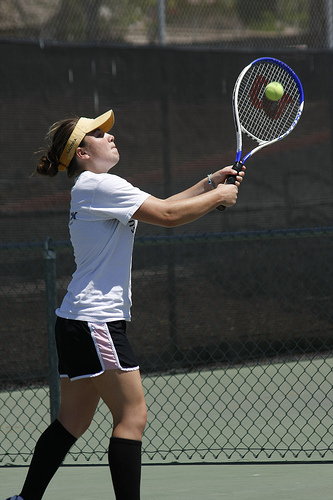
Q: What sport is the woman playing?
A: Tennis.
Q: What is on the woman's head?
A: Visor.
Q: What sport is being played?
A: Tennis.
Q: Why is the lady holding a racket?
A: To hit the ball.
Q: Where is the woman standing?
A: On a tennis court.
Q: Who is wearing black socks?
A: Tennis player.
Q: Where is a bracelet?
A: Around woman's wrist.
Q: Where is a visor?
A: On woman's head.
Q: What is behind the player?
A: A fence.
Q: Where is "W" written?
A: On tennis racket.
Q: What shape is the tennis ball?
A: Round.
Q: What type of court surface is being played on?
A: Hard.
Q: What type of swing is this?
A: Backhand.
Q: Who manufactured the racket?
A: Wilson.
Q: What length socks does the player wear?
A: Knee length.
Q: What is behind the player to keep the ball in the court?
A: A fence.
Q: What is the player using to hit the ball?
A: Tennis Racket.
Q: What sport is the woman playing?
A: Tennis.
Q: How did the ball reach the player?
A: Another player hit it.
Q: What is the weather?
A: Sunny.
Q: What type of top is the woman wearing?
A: T-shirt.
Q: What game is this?
A: Tennis.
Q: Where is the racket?
A: On the player's hands.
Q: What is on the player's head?
A: A yellow hat.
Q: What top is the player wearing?
A: A white tee.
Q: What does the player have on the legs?
A: Black socks.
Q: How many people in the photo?
A: One.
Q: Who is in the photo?
A: A woman.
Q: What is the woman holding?
A: A racket.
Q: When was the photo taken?
A: Day time.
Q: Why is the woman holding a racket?
A: To hit the ball.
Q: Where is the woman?
A: A court.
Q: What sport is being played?
A: Tennis.